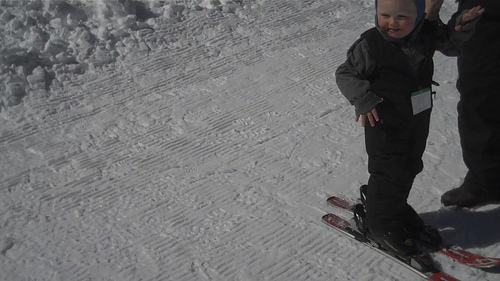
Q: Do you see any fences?
A: No, there are no fences.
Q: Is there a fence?
A: No, there are no fences.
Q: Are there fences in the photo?
A: No, there are no fences.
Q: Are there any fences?
A: No, there are no fences.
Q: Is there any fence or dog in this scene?
A: No, there are no fences or dogs.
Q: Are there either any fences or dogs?
A: No, there are no fences or dogs.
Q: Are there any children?
A: Yes, there is a child.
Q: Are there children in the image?
A: Yes, there is a child.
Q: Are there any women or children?
A: Yes, there is a child.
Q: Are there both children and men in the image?
A: No, there is a child but no men.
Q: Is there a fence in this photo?
A: No, there are no fences.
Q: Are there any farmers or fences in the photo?
A: No, there are no fences or farmers.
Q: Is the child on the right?
A: Yes, the child is on the right of the image.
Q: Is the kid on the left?
A: No, the kid is on the right of the image.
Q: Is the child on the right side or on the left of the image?
A: The child is on the right of the image.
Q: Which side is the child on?
A: The child is on the right of the image.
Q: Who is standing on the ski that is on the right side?
A: The child is standing on the ski.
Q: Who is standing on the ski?
A: The child is standing on the ski.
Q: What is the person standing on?
A: The kid is standing on the ski.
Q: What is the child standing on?
A: The kid is standing on the ski.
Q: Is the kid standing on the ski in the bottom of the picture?
A: Yes, the kid is standing on the ski.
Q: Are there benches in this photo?
A: No, there are no benches.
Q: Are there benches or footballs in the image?
A: No, there are no benches or footballs.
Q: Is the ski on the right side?
A: Yes, the ski is on the right of the image.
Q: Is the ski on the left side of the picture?
A: No, the ski is on the right of the image.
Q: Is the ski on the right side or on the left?
A: The ski is on the right of the image.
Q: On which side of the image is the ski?
A: The ski is on the right of the image.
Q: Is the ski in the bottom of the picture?
A: Yes, the ski is in the bottom of the image.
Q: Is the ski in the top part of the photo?
A: No, the ski is in the bottom of the image.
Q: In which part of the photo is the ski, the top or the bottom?
A: The ski is in the bottom of the image.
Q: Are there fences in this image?
A: No, there are no fences.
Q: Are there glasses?
A: No, there are no glasses.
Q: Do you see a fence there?
A: No, there are no fences.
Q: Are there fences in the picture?
A: No, there are no fences.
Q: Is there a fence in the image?
A: No, there are no fences.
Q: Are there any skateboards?
A: No, there are no skateboards.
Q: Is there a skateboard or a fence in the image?
A: No, there are no skateboards or fences.